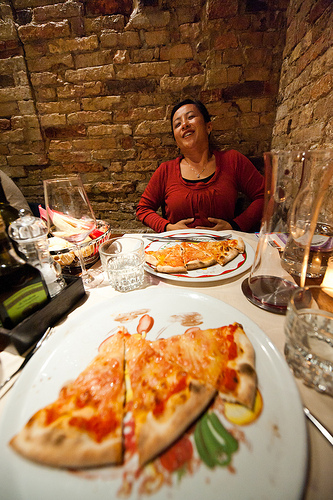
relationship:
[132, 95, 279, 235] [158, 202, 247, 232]
woman with hands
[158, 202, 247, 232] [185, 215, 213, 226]
hands on stomach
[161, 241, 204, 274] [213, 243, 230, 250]
pizza slice with toppings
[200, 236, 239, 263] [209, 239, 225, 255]
pizza slice with toppings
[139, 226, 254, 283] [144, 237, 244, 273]
plate under pizza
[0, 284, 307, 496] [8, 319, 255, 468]
plate under pizza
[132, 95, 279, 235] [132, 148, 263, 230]
woman wearing shirt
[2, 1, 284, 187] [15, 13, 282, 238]
brick on wall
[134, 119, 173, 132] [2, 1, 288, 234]
brick on wall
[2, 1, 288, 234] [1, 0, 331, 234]
wall of building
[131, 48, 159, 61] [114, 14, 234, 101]
brick on wall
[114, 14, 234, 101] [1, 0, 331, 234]
wall of building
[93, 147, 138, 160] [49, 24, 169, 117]
brick on wall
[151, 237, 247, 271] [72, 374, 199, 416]
pizza with toppings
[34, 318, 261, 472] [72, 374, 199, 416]
pizza with toppings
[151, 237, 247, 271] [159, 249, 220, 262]
pizza with toppings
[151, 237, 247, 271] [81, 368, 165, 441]
pizza with toppings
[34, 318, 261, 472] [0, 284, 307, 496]
pizza on plate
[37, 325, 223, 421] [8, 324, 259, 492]
cheese on pizza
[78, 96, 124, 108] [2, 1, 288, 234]
brick on wall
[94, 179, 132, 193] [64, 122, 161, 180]
brick on wall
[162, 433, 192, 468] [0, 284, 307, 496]
pepperoni on plate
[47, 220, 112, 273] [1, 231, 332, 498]
basket on table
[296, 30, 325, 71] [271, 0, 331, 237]
brick on wall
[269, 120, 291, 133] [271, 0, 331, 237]
brick on wall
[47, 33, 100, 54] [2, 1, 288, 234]
brick on wall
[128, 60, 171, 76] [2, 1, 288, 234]
brick on wall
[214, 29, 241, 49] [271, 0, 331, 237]
brick on wall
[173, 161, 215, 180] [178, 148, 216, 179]
jewelry on neck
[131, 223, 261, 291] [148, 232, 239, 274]
plate with pizza slices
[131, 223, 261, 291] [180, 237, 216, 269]
plate with pizza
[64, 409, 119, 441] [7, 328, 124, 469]
topping baked into pizza slice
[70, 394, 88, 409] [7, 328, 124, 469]
topping baked into pizza slice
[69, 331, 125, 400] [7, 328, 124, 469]
topping baked into pizza slice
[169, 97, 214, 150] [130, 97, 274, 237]
head belonging to lady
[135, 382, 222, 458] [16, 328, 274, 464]
crust bordering pizza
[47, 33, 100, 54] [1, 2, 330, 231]
brick supporting wall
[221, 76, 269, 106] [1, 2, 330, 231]
brick supporting wall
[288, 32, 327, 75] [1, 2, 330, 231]
brick supporting wall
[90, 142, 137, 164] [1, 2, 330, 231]
brick supporting wall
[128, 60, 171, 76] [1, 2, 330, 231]
brick supporting wall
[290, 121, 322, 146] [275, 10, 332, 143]
brick supporting brick wall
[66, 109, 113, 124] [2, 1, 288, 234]
brick supporting wall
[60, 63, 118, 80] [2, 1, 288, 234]
brick supporting wall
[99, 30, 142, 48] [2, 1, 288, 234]
brick supporting wall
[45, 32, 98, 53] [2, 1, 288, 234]
brick supporting wall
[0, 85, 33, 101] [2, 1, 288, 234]
brick supporting wall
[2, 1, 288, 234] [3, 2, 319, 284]
wall supporting building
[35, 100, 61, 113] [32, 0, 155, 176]
brick supporting wall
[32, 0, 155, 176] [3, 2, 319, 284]
wall supporting building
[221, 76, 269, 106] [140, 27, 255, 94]
brick on a wall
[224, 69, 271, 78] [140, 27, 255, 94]
brick on a wall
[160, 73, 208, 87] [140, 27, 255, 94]
brick on a wall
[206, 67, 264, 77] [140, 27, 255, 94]
brick on a wall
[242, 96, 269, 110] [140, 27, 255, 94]
brick on a wall